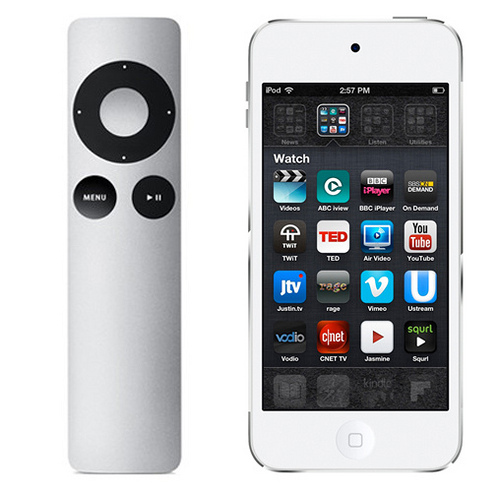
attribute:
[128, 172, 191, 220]
button — Play pause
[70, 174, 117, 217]
menu button — Black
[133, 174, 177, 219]
button — player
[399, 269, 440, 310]
button — U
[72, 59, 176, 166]
directional button — Directional 